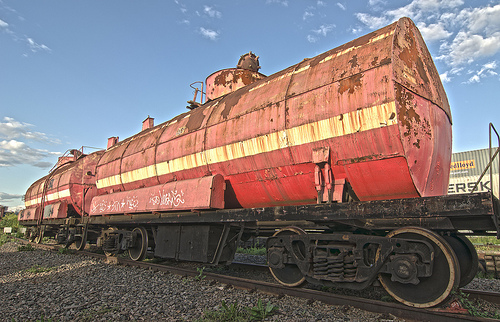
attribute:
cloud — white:
[196, 25, 221, 42]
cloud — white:
[461, 62, 498, 87]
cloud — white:
[442, 27, 499, 67]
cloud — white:
[313, 21, 335, 38]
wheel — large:
[306, 217, 472, 302]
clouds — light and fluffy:
[425, 9, 490, 42]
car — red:
[5, 15, 498, 308]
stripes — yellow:
[88, 96, 423, 189]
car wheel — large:
[269, 227, 314, 292]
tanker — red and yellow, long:
[61, 26, 466, 231]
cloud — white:
[182, 5, 219, 41]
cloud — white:
[357, 2, 487, 67]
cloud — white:
[3, 116, 71, 171]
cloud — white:
[2, 6, 53, 56]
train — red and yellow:
[59, 56, 424, 215]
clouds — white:
[16, 60, 49, 89]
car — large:
[14, 35, 479, 310]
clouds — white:
[2, 116, 63, 169]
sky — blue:
[1, 0, 499, 206]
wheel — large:
[92, 224, 123, 253]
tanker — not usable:
[90, 16, 450, 216]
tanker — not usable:
[18, 146, 105, 220]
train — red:
[87, 58, 474, 193]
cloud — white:
[364, 1, 480, 61]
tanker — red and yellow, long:
[10, 130, 104, 245]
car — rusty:
[78, 23, 471, 251]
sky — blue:
[4, 0, 484, 178]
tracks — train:
[47, 230, 497, 319]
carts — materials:
[29, 160, 293, 211]